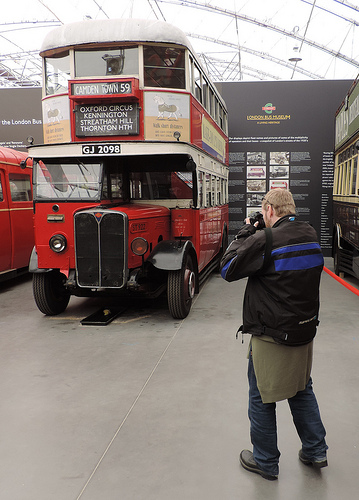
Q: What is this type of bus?
A: Double decker.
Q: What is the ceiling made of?
A: Glass.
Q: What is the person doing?
A: Taking pictures.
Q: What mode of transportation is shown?
A: Bus.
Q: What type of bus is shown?
A: Double decker bus.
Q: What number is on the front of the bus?
A: 59.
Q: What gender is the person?
A: Male.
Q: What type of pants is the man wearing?
A: Jeans.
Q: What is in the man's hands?
A: Camera.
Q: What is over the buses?
A: Roof.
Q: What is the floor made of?
A: Concrete.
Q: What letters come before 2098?
A: GJ.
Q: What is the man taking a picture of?
A: A double decker bus.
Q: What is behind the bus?
A: An informational wall.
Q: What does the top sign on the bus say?
A: Camden Town 59.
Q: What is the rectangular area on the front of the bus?
A: A radiator.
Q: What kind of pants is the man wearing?
A: Jeans.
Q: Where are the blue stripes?
A: On the man's jacket.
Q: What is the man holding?
A: A camera.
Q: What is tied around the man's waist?
A: A sweater.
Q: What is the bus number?
A: GJ 2098.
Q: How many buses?
A: 2.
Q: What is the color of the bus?
A: Red.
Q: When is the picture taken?
A: Daytime.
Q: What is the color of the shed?
A: Black.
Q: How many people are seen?
A: 1.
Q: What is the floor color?
A: Grey.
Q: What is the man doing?
A: Taking photo.